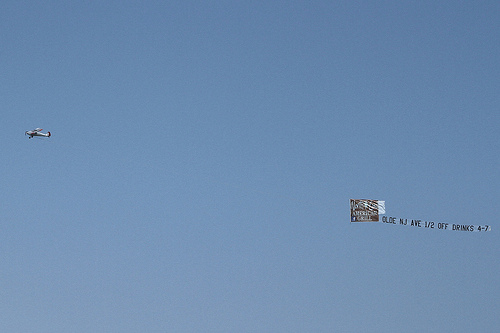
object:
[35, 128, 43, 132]
wing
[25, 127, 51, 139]
airplane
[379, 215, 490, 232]
string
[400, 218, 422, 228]
nj ave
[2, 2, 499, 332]
sky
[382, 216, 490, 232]
words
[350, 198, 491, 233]
advertisement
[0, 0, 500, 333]
air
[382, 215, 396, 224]
letters